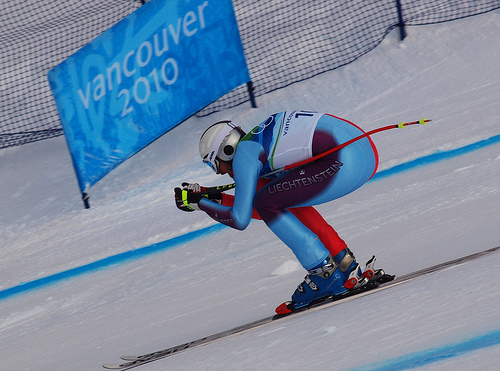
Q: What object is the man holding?
A: Ski pole.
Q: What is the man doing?
A: Skiing.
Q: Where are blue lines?
A: Painted on the snow.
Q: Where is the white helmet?
A: On the man's head.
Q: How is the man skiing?
A: Crouched down.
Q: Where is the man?
A: On a ski slope.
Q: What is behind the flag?
A: A mesh fence.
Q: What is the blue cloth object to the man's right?
A: Flag.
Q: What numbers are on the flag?
A: 2010.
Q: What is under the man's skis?
A: Snow.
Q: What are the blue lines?
A: Boundary lines.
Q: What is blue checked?
A: The snow fence.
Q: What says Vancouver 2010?
A: The blue sign.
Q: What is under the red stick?
A: White lettering on the ski suit.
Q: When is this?
A: Daytime.